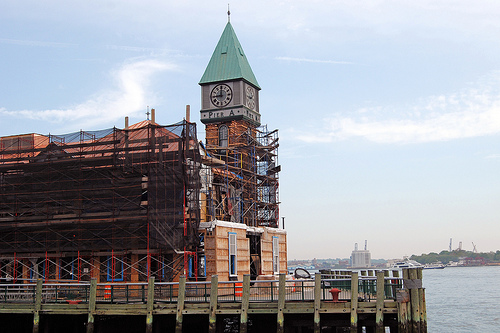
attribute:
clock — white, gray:
[209, 83, 234, 109]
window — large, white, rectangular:
[228, 232, 238, 278]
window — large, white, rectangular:
[272, 235, 281, 275]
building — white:
[350, 249, 373, 269]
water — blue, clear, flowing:
[420, 264, 499, 331]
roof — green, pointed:
[198, 21, 263, 90]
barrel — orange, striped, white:
[234, 281, 245, 297]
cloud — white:
[2, 57, 183, 127]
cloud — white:
[295, 86, 497, 147]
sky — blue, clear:
[1, 0, 499, 259]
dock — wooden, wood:
[1, 267, 429, 332]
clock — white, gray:
[246, 85, 258, 108]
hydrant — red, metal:
[328, 288, 346, 304]